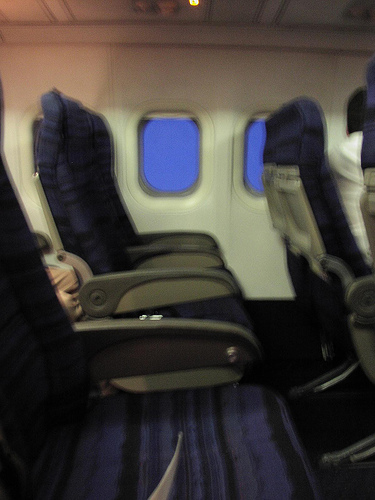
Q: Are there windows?
A: Yes, there is a window.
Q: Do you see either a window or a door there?
A: Yes, there is a window.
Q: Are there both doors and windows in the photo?
A: No, there is a window but no doors.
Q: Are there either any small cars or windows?
A: Yes, there is a small window.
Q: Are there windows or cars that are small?
A: Yes, the window is small.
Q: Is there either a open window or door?
A: Yes, there is an open window.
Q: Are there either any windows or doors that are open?
A: Yes, the window is open.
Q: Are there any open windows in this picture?
A: Yes, there is an open window.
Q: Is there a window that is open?
A: Yes, there is a window that is open.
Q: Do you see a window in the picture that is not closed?
A: Yes, there is a open window.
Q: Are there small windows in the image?
A: Yes, there is a small window.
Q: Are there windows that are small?
A: Yes, there is a window that is small.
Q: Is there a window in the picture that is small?
A: Yes, there is a window that is small.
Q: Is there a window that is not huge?
A: Yes, there is a small window.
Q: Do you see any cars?
A: No, there are no cars.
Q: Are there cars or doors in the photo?
A: No, there are no cars or doors.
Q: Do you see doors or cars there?
A: No, there are no cars or doors.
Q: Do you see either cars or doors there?
A: No, there are no cars or doors.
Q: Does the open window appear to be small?
A: Yes, the window is small.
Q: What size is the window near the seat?
A: The window is small.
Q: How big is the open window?
A: The window is small.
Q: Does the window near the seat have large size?
A: No, the window is small.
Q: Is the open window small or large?
A: The window is small.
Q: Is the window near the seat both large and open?
A: No, the window is open but small.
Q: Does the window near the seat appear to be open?
A: Yes, the window is open.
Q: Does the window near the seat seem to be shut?
A: No, the window is open.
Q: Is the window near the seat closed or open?
A: The window is open.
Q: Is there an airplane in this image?
A: Yes, there is an airplane.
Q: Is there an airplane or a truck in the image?
A: Yes, there is an airplane.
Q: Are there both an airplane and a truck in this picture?
A: No, there is an airplane but no trucks.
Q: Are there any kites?
A: No, there are no kites.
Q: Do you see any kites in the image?
A: No, there are no kites.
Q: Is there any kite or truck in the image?
A: No, there are no kites or trucks.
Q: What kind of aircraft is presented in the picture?
A: The aircraft is an airplane.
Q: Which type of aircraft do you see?
A: The aircraft is an airplane.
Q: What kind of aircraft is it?
A: The aircraft is an airplane.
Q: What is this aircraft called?
A: This is an airplane.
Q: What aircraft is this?
A: This is an airplane.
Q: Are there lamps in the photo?
A: No, there are no lamps.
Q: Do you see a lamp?
A: No, there are no lamps.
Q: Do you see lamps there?
A: No, there are no lamps.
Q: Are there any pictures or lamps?
A: No, there are no lamps or pictures.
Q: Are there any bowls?
A: No, there are no bowls.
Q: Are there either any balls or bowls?
A: No, there are no bowls or balls.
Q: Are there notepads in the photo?
A: No, there are no notepads.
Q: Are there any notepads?
A: No, there are no notepads.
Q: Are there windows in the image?
A: Yes, there is a window.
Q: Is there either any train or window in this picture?
A: Yes, there is a window.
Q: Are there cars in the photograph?
A: No, there are no cars.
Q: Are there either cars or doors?
A: No, there are no cars or doors.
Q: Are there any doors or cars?
A: No, there are no cars or doors.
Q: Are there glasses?
A: No, there are no glasses.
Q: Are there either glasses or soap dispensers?
A: No, there are no glasses or soap dispensers.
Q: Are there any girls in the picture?
A: No, there are no girls.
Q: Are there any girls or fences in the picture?
A: No, there are no girls or fences.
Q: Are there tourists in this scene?
A: No, there are no tourists.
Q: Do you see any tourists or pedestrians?
A: No, there are no tourists or pedestrians.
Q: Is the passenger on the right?
A: Yes, the passenger is on the right of the image.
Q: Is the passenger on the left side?
A: No, the passenger is on the right of the image.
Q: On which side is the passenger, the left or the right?
A: The passenger is on the right of the image.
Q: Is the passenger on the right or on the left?
A: The passenger is on the right of the image.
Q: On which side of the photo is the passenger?
A: The passenger is on the right of the image.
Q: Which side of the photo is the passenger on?
A: The passenger is on the right of the image.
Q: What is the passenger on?
A: The passenger is on the plane.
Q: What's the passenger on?
A: The passenger is on the plane.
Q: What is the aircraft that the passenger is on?
A: The aircraft is an airplane.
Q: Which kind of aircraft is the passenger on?
A: The passenger is on the plane.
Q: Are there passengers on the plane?
A: Yes, there is a passenger on the plane.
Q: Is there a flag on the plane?
A: No, there is a passenger on the plane.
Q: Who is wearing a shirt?
A: The passenger is wearing a shirt.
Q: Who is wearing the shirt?
A: The passenger is wearing a shirt.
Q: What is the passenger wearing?
A: The passenger is wearing a shirt.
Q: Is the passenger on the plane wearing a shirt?
A: Yes, the passenger is wearing a shirt.